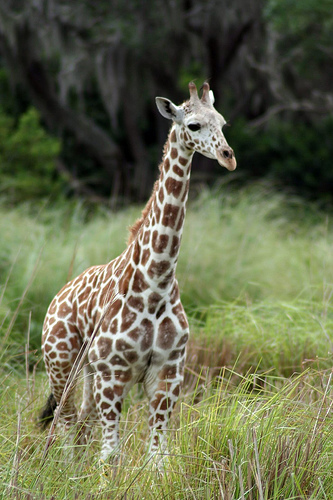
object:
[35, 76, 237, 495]
giraffe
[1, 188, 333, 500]
field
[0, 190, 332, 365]
weeds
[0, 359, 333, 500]
grass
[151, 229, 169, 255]
spots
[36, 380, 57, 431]
tail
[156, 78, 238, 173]
head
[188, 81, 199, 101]
horns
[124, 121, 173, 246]
mane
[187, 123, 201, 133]
eye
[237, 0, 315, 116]
trees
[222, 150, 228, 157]
nostrils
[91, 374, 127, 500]
leg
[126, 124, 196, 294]
neck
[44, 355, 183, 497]
four legs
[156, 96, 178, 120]
ear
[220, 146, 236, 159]
nose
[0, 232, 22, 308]
bud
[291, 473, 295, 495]
single blade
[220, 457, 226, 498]
several blades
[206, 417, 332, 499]
brown grass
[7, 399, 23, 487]
yellow strand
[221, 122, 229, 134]
eyes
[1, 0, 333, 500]
wilderness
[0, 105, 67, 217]
green bush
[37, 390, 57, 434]
hair